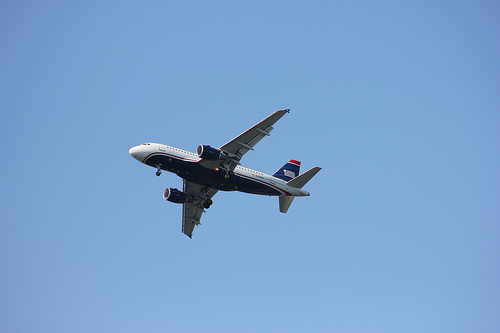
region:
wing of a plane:
[216, 106, 289, 160]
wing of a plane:
[181, 173, 220, 237]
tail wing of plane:
[285, 163, 320, 188]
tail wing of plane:
[273, 190, 293, 211]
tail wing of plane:
[272, 157, 297, 178]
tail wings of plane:
[272, 158, 322, 215]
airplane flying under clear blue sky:
[45, 32, 440, 287]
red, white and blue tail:
[271, 155, 298, 186]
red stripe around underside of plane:
[126, 145, 287, 197]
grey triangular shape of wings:
[175, 105, 287, 240]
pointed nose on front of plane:
[125, 135, 155, 160]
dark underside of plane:
[141, 150, 281, 200]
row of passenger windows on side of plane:
[161, 140, 261, 176]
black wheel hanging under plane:
[150, 135, 162, 175]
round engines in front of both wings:
[160, 140, 220, 201]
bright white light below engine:
[195, 140, 225, 175]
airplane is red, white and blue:
[126, 107, 321, 238]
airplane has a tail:
[272, 157, 302, 182]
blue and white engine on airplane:
[195, 144, 220, 161]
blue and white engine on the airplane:
[162, 187, 187, 204]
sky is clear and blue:
[0, 0, 499, 332]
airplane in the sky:
[0, 0, 497, 331]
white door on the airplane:
[269, 174, 276, 185]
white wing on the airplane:
[196, 108, 287, 173]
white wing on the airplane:
[180, 177, 219, 239]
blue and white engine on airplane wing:
[195, 108, 288, 173]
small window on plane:
[164, 144, 169, 149]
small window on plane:
[167, 144, 172, 149]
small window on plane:
[176, 148, 182, 151]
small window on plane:
[182, 148, 186, 153]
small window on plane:
[191, 151, 194, 156]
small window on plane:
[236, 165, 242, 170]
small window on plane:
[241, 166, 244, 171]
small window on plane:
[245, 168, 250, 173]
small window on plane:
[248, 168, 252, 173]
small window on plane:
[256, 171, 261, 175]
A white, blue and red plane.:
[129, 109, 321, 239]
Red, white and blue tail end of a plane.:
[270, 159, 301, 184]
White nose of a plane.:
[127, 147, 141, 159]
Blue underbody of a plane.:
[144, 152, 280, 198]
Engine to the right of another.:
[195, 144, 222, 162]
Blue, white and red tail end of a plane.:
[272, 158, 302, 183]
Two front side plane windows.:
[140, 142, 152, 147]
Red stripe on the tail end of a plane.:
[286, 158, 301, 168]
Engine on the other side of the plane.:
[160, 187, 195, 205]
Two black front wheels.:
[153, 166, 161, 176]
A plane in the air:
[107, 121, 329, 246]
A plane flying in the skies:
[114, 89, 346, 239]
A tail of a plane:
[264, 149, 309, 190]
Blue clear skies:
[346, 23, 442, 113]